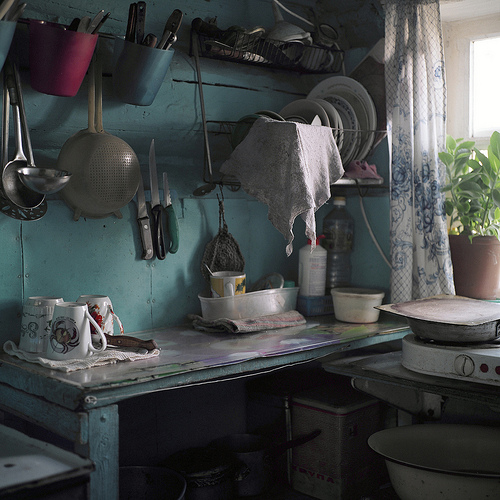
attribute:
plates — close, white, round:
[230, 62, 375, 188]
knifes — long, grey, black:
[129, 134, 173, 256]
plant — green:
[424, 134, 498, 231]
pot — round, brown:
[443, 230, 499, 301]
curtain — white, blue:
[373, 7, 461, 296]